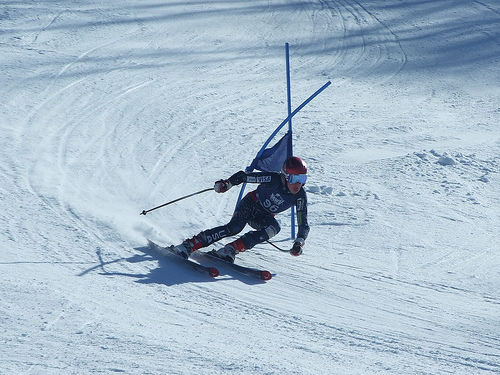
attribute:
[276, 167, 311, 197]
googles — ski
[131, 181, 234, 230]
ski pole — black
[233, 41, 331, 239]
banner — bent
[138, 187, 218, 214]
pole — ski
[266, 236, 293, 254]
pole — ski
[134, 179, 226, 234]
pole — black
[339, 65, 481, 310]
snow — cold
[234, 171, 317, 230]
top — black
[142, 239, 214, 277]
ski — red, white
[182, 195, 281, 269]
ski pants — black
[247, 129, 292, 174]
flag — blue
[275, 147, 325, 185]
helmet — red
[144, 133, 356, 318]
skier — athletic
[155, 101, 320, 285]
skier — athletic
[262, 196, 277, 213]
96 — number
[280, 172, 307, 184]
goggles — silver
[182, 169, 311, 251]
outfit — ski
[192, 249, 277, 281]
red skis — red , black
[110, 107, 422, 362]
person — athletic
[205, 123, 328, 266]
skier — athletic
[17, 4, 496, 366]
trail — curvy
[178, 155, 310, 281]
person — wearing helmet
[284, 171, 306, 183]
goggles — white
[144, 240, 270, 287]
ski shoes — black, red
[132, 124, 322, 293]
skier — athletic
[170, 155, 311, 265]
skier — athletic